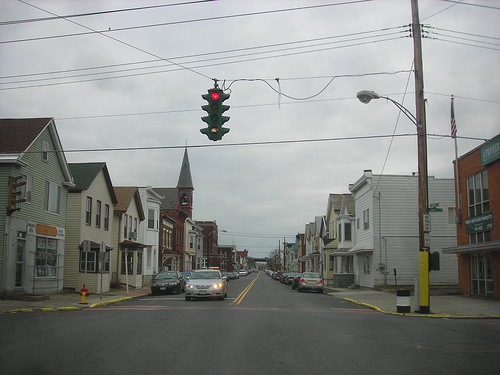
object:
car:
[180, 263, 232, 300]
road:
[11, 291, 493, 375]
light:
[198, 79, 231, 141]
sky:
[1, 2, 500, 129]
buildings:
[2, 112, 77, 301]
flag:
[446, 87, 461, 139]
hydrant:
[74, 282, 93, 305]